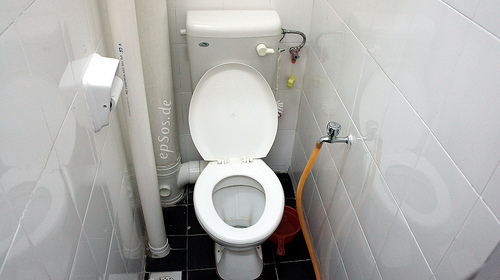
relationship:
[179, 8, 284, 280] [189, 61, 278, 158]
toilet has lid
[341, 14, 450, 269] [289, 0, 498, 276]
reflection on wall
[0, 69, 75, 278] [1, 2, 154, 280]
reflection on wall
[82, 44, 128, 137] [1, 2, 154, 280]
holder on wall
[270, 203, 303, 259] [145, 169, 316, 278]
pan on floor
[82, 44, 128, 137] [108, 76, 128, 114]
holder next to tissue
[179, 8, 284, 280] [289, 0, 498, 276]
toilet next to wall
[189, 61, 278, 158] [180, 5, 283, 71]
lid next to tank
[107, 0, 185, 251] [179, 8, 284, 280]
pipe next to toilet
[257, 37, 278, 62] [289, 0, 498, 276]
handle next to wall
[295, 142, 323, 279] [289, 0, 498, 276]
hose next to wall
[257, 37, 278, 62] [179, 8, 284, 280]
handle on toilet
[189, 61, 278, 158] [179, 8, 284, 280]
lid on toilet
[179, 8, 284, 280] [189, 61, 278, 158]
toilet next to lid